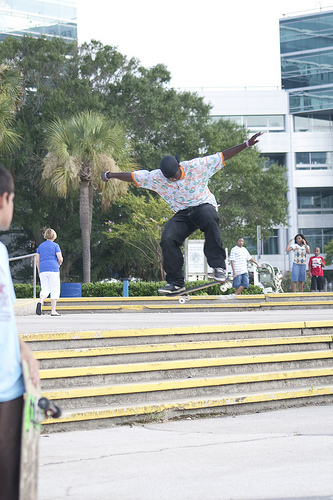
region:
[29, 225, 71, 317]
woman with a blue shirt walking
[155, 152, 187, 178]
black rag on the skater's head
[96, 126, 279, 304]
man with colorful shirt is on a skateboard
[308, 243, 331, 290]
young boy with red shirt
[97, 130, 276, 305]
man on his skateboard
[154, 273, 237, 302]
skateboard in the air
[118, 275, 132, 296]
blue and black pole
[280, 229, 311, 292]
young woman on the phone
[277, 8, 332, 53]
blue windows on the building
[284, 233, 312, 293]
young woman wearing a blue jean skirt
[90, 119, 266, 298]
Skater on street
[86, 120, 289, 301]
Skater wears black pants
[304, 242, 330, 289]
Kid wearing a red shirt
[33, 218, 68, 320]
Old woman with blue shirt walking in park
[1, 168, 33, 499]
Boy is looking the skater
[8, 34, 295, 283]
Big trees in the parl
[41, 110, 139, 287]
A palm in the park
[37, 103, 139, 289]
Palm has dry leaves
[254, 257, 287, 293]
Green baby stroller in the park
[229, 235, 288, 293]
Man holds with his left arm a stroller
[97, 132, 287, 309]
boy on a skateboard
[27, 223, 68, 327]
backside of a lady walking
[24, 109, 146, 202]
top of a palm tree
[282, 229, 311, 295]
girl watching the skateboarder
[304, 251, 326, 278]
red shirt with white picture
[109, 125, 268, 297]
boy with his arms in the air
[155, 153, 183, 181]
baseball cap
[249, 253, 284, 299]
childs stroller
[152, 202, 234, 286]
blue pants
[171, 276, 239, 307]
skateboard with four wheels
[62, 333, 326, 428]
The steps are trimmed in yellow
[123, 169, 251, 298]
A man is on a skateboard.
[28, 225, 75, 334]
A lady walking up the steps.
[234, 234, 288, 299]
The man is pushing the stroller.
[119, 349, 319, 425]
The steps are dirty.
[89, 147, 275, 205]
The man arms are stretched out.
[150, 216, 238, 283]
The guy has on black pants.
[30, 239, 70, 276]
The lady is wearing a blue shirt.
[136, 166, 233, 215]
The man is wearing a white, orange and green shirt.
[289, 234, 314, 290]
A woman is talking on a cellphone.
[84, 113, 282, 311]
boy on skateboard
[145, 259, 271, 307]
black skateboard with white wheels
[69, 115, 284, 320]
boy on skateboard in the air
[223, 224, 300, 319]
man pushing stroller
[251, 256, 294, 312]
green stroller parked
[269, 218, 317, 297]
lady on the phone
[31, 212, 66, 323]
lady walking up stairs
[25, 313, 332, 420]
flight of stairs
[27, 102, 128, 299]
palm tree in park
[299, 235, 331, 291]
boy with red shirt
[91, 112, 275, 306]
man on a skateboard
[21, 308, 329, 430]
a set of steps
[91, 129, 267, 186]
man has arms raised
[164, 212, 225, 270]
black pants worn by man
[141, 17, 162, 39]
white clouds in blue sky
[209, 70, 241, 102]
white clouds in blue sky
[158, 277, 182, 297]
black and white shoe worn by man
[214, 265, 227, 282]
a boy's black and white tennis shoe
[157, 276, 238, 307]
a black and white skateboard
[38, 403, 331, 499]
a paved sidewalk